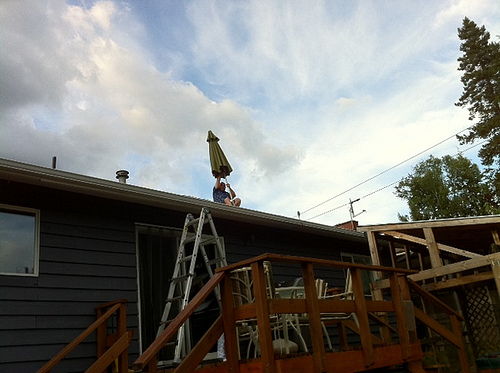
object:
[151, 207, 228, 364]
ladder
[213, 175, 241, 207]
man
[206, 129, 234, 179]
umbrella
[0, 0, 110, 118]
clouds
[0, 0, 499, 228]
sky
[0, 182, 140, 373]
wall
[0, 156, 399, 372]
house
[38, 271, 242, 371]
stairs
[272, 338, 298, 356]
box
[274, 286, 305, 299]
table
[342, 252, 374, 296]
curtain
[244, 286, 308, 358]
chair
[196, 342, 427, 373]
floor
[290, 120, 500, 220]
wires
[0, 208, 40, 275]
window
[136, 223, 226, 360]
door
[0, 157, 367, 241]
roof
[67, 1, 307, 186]
cloud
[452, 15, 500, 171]
tree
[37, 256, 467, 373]
railing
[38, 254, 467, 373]
deck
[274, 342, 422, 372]
wood